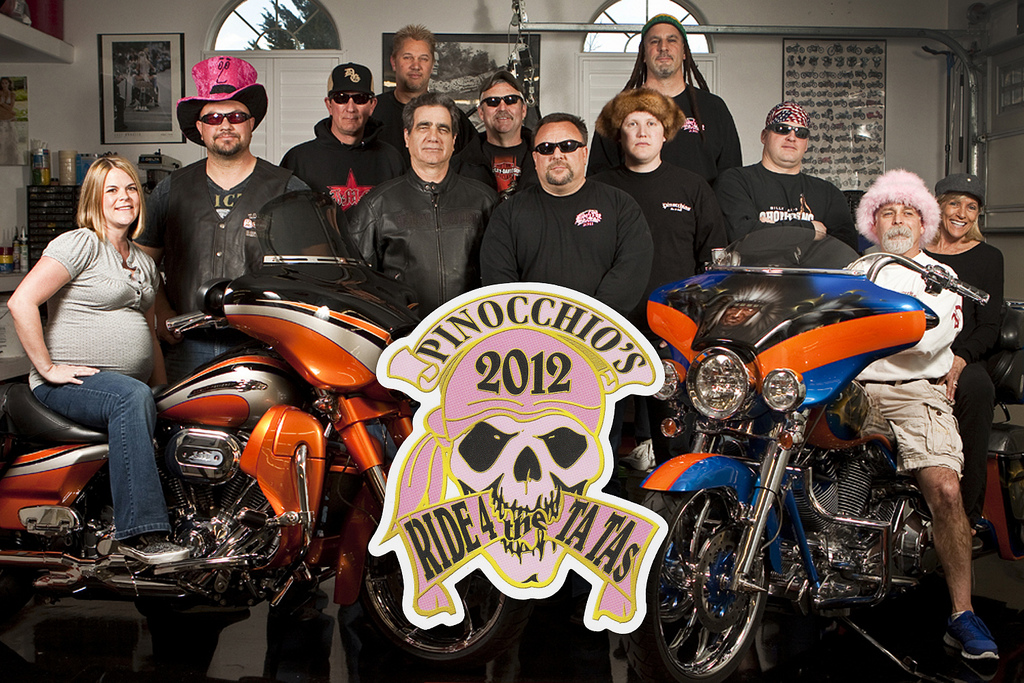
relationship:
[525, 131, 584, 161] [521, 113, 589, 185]
sunglasses on face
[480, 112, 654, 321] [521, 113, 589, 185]
man has face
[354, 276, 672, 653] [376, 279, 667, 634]
skull on sign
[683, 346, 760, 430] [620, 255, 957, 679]
light of motorcycle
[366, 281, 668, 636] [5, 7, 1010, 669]
skull in front of people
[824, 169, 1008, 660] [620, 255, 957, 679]
man sitting on motorcycle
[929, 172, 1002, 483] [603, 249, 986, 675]
woman standing behind motorcycle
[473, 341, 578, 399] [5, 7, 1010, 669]
2012 in front of people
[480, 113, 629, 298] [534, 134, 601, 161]
man wearing sun glasses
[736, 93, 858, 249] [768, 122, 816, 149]
man wearing sun glasses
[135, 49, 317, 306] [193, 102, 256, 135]
man wearing sun glasses